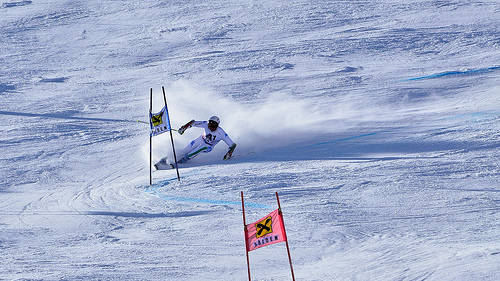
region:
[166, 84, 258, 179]
person in the snow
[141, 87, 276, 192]
person wearing snow gear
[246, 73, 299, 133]
white snow in the air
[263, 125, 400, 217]
tracks in the snow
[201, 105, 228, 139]
head of the person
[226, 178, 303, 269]
sign in the snow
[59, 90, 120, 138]
shadow on the ground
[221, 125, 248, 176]
arm of the person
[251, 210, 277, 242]
yellow icon on sign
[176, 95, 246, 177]
person wearing white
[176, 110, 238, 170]
this is a man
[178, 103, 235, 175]
the man is snow skating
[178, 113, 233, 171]
the man is bending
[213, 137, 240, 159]
this is the hand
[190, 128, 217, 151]
the costume is white in color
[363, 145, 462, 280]
the snow is all over the place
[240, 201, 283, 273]
this is a flag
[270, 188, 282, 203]
the stick is thin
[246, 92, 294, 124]
the snow is splashy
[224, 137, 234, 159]
the hand is bent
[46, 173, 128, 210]
Tracks from skis in the snow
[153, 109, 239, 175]
A person skiing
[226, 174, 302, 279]
Pink marker on a ski slope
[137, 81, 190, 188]
White marker on a ski slope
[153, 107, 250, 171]
A person wearing a white ski suit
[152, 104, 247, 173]
A person skiing at an angle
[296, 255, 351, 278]
White snow on the ground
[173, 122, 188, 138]
Gloved hand holding a ski pole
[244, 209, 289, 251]
Hot pink colored sign with a yellow and black symbol on it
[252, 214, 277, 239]
Yellow and black symbol on a ski sign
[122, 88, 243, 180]
the man is snowboarding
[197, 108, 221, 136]
man wearing a helmet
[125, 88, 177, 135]
sign attached to wooden posts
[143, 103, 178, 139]
the sign is white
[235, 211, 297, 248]
sign attached to posts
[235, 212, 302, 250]
the sign is red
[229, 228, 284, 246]
blue letters on sign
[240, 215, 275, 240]
yellow sign on the sign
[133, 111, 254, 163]
man holding ski poles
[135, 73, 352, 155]
snow going in the air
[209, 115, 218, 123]
White helmet on a skiers head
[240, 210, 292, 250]
Pink flag on a ski course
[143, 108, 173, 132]
White flag on a ski course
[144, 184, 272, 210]
Blue line in the snow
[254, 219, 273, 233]
Black X on a flag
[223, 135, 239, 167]
Person's left hand in the snow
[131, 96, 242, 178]
Person skiing in a contest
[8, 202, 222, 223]
Black shadow in the snow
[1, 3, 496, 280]
Snow covering a ski course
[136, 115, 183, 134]
Ski pole in a person's right hand